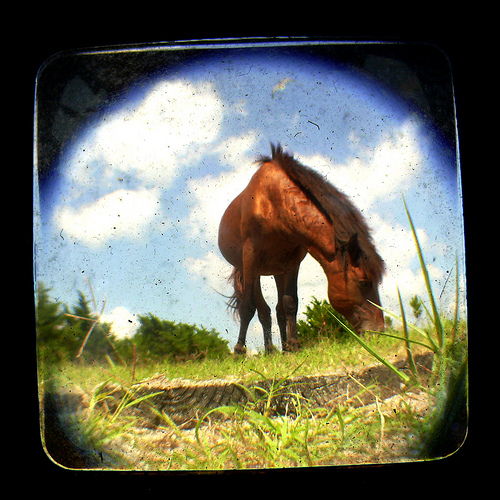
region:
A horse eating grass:
[195, 135, 406, 386]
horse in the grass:
[196, 145, 413, 360]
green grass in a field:
[132, 349, 307, 380]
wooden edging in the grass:
[147, 374, 323, 424]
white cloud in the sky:
[53, 185, 160, 244]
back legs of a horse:
[221, 269, 282, 359]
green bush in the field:
[132, 307, 241, 370]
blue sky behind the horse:
[251, 74, 350, 134]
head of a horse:
[318, 258, 393, 337]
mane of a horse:
[297, 154, 379, 259]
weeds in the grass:
[396, 193, 457, 421]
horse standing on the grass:
[202, 144, 419, 378]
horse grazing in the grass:
[207, 147, 417, 357]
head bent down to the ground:
[318, 239, 402, 340]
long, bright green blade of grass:
[311, 297, 408, 380]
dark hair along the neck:
[240, 138, 386, 281]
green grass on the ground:
[38, 343, 471, 464]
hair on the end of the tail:
[207, 278, 242, 329]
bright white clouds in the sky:
[36, 65, 452, 335]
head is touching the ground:
[321, 245, 398, 343]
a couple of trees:
[36, 277, 396, 363]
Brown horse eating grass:
[223, 153, 384, 344]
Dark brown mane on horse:
[283, 146, 390, 276]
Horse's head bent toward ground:
[333, 258, 387, 339]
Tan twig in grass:
[63, 285, 139, 374]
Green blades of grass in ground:
[406, 195, 447, 377]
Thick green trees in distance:
[133, 314, 225, 354]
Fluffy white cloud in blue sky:
[84, 76, 218, 181]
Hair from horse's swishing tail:
[217, 288, 239, 323]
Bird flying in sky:
[267, 75, 298, 99]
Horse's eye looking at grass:
[359, 275, 367, 287]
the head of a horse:
[323, 235, 413, 348]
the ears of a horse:
[305, 230, 385, 270]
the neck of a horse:
[268, 195, 353, 280]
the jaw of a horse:
[311, 275, 351, 339]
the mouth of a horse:
[328, 301, 395, 346]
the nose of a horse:
[365, 301, 415, 343]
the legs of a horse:
[213, 255, 313, 376]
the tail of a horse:
[216, 240, 258, 330]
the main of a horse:
[270, 169, 362, 334]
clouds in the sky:
[111, 128, 241, 303]